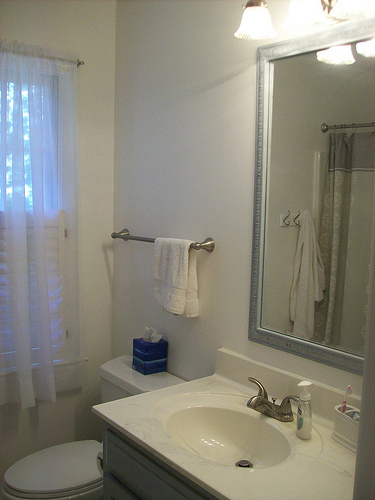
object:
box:
[132, 338, 169, 376]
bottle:
[296, 380, 312, 440]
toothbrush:
[341, 384, 353, 412]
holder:
[329, 402, 359, 453]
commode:
[102, 419, 221, 500]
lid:
[4, 438, 101, 493]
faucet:
[246, 377, 300, 422]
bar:
[110, 227, 214, 253]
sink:
[90, 347, 362, 500]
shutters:
[0, 343, 65, 372]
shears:
[0, 36, 89, 411]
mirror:
[247, 18, 374, 379]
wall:
[111, 0, 375, 398]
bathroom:
[0, 0, 375, 500]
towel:
[152, 236, 200, 318]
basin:
[165, 402, 295, 471]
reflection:
[278, 122, 374, 358]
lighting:
[233, 0, 375, 40]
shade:
[233, 5, 277, 40]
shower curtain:
[309, 121, 375, 355]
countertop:
[90, 372, 361, 500]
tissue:
[141, 325, 164, 343]